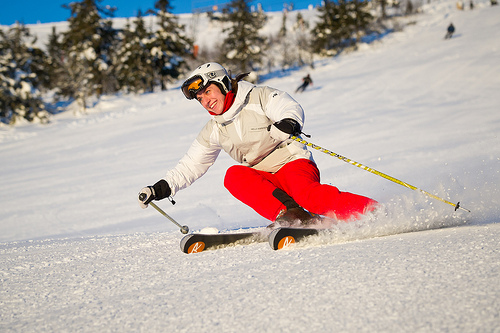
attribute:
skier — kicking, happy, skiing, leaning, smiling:
[129, 54, 399, 255]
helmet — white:
[182, 57, 236, 92]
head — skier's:
[183, 55, 234, 113]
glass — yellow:
[184, 76, 203, 88]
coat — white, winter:
[146, 86, 302, 193]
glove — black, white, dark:
[141, 178, 178, 206]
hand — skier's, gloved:
[138, 176, 174, 208]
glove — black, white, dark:
[264, 115, 306, 144]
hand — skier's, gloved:
[261, 115, 304, 141]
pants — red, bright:
[219, 164, 375, 226]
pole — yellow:
[296, 135, 462, 209]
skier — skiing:
[289, 72, 317, 93]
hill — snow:
[336, 44, 498, 173]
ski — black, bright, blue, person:
[180, 232, 265, 256]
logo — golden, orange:
[185, 240, 208, 254]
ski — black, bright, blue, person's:
[266, 225, 326, 247]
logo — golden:
[273, 235, 297, 251]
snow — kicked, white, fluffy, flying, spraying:
[335, 201, 497, 242]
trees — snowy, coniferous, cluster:
[8, 0, 384, 59]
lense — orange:
[180, 74, 211, 91]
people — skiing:
[298, 67, 327, 89]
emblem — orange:
[274, 233, 301, 257]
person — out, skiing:
[143, 58, 375, 223]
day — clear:
[6, 7, 498, 237]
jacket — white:
[198, 95, 321, 180]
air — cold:
[5, 0, 497, 305]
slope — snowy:
[305, 49, 499, 178]